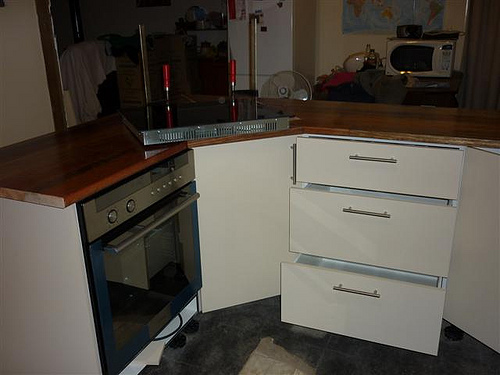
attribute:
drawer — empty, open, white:
[297, 139, 458, 196]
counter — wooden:
[292, 97, 499, 148]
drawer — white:
[287, 268, 435, 352]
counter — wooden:
[7, 118, 153, 197]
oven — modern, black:
[82, 150, 203, 373]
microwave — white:
[385, 31, 455, 78]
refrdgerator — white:
[225, 0, 312, 90]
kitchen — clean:
[18, 4, 491, 370]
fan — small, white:
[262, 66, 313, 102]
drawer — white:
[290, 192, 450, 275]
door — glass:
[104, 229, 198, 333]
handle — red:
[225, 60, 238, 93]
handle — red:
[159, 69, 174, 98]